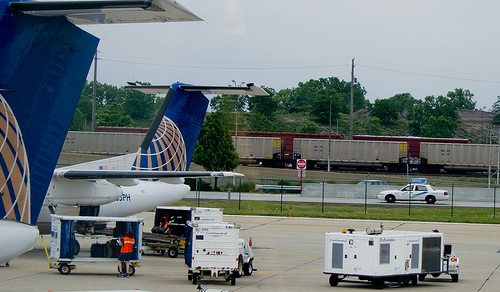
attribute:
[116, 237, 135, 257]
vest — orange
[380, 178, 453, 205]
taxi — blue and white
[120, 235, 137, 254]
vest — safety vest 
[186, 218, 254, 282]
truck — work truck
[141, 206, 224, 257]
truck — work truck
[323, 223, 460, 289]
truck — work truck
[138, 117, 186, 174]
globe — golden colored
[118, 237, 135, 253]
vest — orange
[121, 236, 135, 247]
stripe — yellow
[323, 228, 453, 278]
vehicle — white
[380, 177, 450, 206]
car — white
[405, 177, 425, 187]
sign — blue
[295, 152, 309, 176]
sign — red, white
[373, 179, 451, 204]
car — white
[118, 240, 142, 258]
vest — orange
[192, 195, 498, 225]
grass — green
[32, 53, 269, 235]
airplane — blue